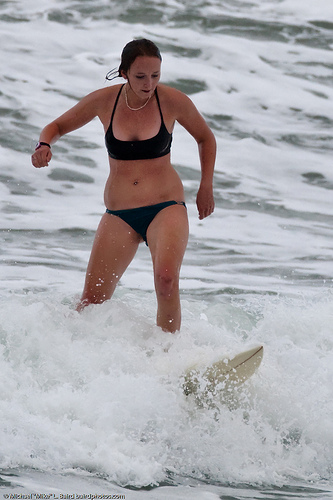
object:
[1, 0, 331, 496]
water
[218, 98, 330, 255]
white foam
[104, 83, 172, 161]
black top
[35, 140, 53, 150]
wrist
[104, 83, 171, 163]
top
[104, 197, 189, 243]
black bottom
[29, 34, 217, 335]
woman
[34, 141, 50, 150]
black watch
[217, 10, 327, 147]
ocean waves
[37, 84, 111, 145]
arm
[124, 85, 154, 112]
necklace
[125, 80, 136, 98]
neck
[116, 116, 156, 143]
chest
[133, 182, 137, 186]
belly button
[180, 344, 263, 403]
board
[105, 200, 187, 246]
bikini